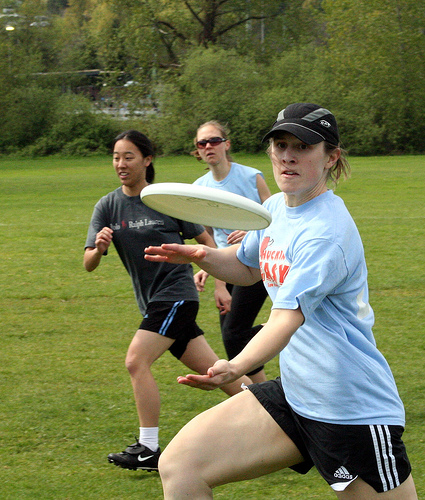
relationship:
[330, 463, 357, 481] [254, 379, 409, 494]
adidas symbol in pants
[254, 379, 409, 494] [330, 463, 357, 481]
pants have adidas symbol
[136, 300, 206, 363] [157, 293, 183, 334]
shorts have stripes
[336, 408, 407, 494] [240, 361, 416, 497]
stripes on pair of shorts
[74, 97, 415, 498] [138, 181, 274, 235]
people playing with frisbee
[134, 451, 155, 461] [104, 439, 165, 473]
logo on shoe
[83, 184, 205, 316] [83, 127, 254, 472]
shirt on woman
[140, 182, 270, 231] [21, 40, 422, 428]
frisbee flying through air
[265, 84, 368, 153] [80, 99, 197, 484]
hat on woman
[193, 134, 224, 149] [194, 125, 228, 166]
sunglasses on face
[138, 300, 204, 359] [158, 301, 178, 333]
shorts with stripe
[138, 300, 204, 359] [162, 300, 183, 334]
shorts with stripe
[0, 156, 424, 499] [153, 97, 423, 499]
grass beneath people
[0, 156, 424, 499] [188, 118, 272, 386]
grass beneath woman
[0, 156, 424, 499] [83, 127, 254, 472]
grass beneath woman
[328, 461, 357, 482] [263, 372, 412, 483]
adidas symbol on shorts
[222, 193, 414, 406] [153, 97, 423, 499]
shirt on people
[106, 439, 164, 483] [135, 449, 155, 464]
cleats with logo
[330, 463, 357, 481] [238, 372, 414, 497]
adidas symbol on pants